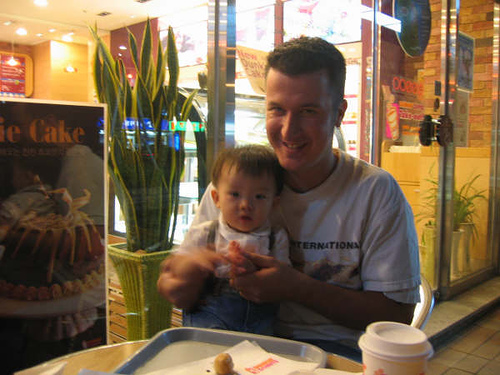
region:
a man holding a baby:
[157, 31, 443, 331]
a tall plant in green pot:
[92, 29, 192, 328]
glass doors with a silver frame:
[424, 8, 489, 270]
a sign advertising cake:
[10, 101, 115, 348]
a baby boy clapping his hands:
[174, 144, 286, 331]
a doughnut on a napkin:
[209, 339, 272, 374]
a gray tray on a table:
[158, 324, 200, 373]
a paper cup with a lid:
[352, 323, 433, 374]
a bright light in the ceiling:
[14, 16, 39, 41]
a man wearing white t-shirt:
[280, 43, 422, 323]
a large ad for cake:
[5, 118, 96, 326]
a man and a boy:
[140, 33, 477, 335]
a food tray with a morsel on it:
[113, 323, 337, 373]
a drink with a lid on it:
[354, 314, 441, 372]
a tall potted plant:
[85, 55, 196, 344]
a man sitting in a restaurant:
[88, 20, 485, 370]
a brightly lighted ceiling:
[3, 2, 328, 85]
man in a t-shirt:
[123, 5, 451, 347]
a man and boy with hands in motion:
[107, 31, 447, 336]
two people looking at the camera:
[124, 36, 454, 342]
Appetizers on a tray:
[189, 332, 229, 372]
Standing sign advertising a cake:
[3, 90, 130, 344]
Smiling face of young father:
[248, 30, 364, 200]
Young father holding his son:
[173, 28, 394, 309]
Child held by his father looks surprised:
[180, 147, 292, 294]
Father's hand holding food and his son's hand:
[182, 232, 294, 316]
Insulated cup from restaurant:
[346, 285, 446, 370]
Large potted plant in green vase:
[77, 9, 189, 339]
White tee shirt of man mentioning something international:
[285, 175, 427, 317]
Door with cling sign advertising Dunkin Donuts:
[375, 67, 473, 163]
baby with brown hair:
[204, 136, 292, 232]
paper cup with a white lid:
[354, 306, 439, 373]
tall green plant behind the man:
[70, 16, 210, 331]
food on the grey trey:
[196, 326, 236, 373]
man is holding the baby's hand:
[216, 237, 311, 310]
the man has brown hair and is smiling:
[250, 31, 359, 173]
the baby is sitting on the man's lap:
[166, 145, 321, 336]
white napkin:
[131, 323, 326, 373]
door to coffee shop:
[371, 1, 496, 308]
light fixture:
[2, 42, 42, 82]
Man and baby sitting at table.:
[160, 28, 435, 344]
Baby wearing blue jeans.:
[171, 252, 283, 338]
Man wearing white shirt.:
[284, 159, 436, 346]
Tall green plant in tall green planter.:
[78, 19, 203, 336]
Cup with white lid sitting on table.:
[357, 318, 438, 373]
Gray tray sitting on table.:
[120, 318, 330, 373]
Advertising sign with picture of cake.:
[1, 102, 107, 348]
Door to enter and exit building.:
[373, 11, 465, 302]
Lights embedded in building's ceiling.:
[15, 4, 80, 42]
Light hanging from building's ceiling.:
[3, 41, 31, 71]